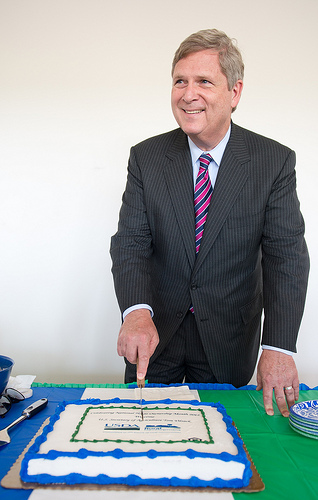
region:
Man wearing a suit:
[109, 25, 311, 417]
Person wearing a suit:
[108, 28, 310, 417]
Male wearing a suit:
[108, 26, 312, 417]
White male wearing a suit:
[107, 26, 309, 416]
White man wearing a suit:
[106, 27, 308, 417]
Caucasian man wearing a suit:
[108, 25, 307, 415]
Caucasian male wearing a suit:
[106, 26, 309, 413]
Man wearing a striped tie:
[108, 25, 311, 418]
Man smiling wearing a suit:
[108, 26, 310, 419]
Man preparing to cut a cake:
[19, 28, 310, 495]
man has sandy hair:
[173, 11, 233, 104]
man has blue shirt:
[172, 134, 230, 184]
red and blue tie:
[187, 155, 220, 264]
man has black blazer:
[100, 106, 308, 397]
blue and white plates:
[283, 391, 312, 440]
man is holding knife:
[129, 355, 150, 416]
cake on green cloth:
[179, 378, 295, 488]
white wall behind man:
[14, 38, 91, 182]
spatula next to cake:
[0, 392, 51, 465]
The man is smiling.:
[161, 26, 265, 145]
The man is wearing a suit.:
[95, 22, 313, 425]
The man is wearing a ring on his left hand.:
[103, 21, 312, 423]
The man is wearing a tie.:
[96, 18, 314, 427]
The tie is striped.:
[176, 146, 230, 318]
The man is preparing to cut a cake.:
[20, 26, 313, 497]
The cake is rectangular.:
[19, 390, 257, 494]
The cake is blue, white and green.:
[18, 389, 256, 492]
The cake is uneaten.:
[15, 385, 259, 495]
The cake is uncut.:
[17, 395, 255, 492]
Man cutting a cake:
[18, 26, 309, 487]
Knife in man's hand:
[116, 306, 159, 422]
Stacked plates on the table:
[289, 399, 317, 442]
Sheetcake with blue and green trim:
[20, 396, 251, 486]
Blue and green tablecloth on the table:
[0, 384, 317, 496]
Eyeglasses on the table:
[0, 383, 26, 418]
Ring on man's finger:
[284, 382, 295, 395]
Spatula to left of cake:
[0, 392, 49, 448]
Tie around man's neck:
[194, 148, 213, 252]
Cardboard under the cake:
[0, 415, 263, 493]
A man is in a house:
[28, 14, 298, 495]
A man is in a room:
[27, 14, 294, 491]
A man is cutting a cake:
[53, 12, 289, 493]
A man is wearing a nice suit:
[35, 12, 297, 489]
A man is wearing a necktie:
[28, 9, 298, 495]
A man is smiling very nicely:
[54, 3, 315, 493]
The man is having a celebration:
[43, 12, 292, 490]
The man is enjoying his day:
[53, 18, 300, 497]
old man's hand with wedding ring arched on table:
[256, 351, 300, 416]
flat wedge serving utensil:
[0, 395, 48, 449]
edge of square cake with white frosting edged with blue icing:
[23, 451, 251, 489]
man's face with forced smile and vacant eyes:
[163, 26, 244, 147]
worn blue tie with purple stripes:
[189, 149, 217, 259]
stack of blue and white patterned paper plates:
[288, 396, 316, 441]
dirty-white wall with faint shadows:
[6, 64, 101, 345]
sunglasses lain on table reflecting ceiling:
[0, 387, 27, 417]